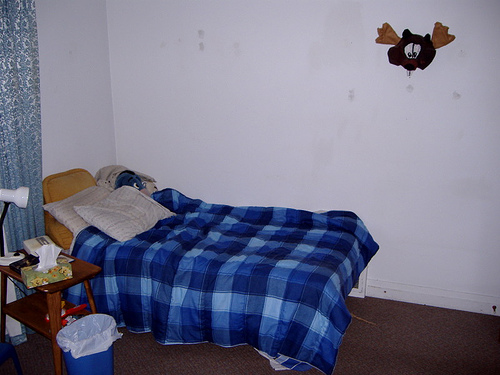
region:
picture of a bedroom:
[9, 61, 398, 373]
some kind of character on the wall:
[354, 5, 464, 93]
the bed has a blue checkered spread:
[36, 142, 382, 357]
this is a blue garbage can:
[34, 287, 134, 372]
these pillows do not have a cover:
[35, 167, 177, 255]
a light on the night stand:
[2, 182, 98, 289]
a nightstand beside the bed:
[1, 237, 141, 368]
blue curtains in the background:
[3, 4, 75, 261]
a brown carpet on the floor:
[71, 250, 496, 366]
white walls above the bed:
[68, 29, 346, 215]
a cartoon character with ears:
[370, 22, 460, 69]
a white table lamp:
[0, 185, 35, 267]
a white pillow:
[79, 184, 179, 236]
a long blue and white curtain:
[0, 0, 46, 334]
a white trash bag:
[58, 312, 126, 354]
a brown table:
[0, 252, 108, 367]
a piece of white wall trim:
[368, 279, 497, 317]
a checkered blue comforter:
[70, 188, 379, 373]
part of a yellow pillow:
[40, 166, 100, 251]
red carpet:
[348, 292, 498, 374]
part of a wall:
[464, 171, 492, 181]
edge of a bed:
[238, 275, 260, 292]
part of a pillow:
[118, 206, 130, 225]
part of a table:
[65, 283, 72, 289]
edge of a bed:
[68, 163, 76, 178]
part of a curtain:
[18, 140, 26, 147]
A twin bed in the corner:
[48, 148, 366, 373]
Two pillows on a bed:
[48, 183, 175, 241]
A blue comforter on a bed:
[86, 183, 381, 354]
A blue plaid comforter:
[105, 191, 368, 353]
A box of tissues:
[18, 243, 75, 291]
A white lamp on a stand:
[1, 163, 38, 268]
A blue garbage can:
[50, 308, 147, 373]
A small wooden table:
[4, 236, 111, 370]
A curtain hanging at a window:
[4, 25, 54, 271]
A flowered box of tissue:
[16, 243, 80, 290]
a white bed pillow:
[76, 183, 176, 243]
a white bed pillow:
[41, 186, 109, 233]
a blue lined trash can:
[55, 309, 120, 372]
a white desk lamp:
[0, 184, 30, 266]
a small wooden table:
[4, 245, 101, 371]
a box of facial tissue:
[16, 243, 76, 291]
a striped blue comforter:
[59, 189, 381, 374]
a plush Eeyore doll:
[113, 170, 149, 197]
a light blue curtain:
[0, 2, 47, 252]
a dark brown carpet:
[0, 286, 499, 371]